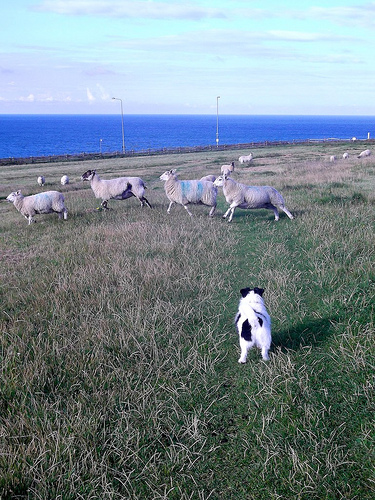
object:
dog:
[238, 283, 283, 375]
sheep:
[84, 166, 134, 195]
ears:
[240, 283, 274, 303]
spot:
[237, 318, 262, 343]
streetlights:
[103, 87, 226, 157]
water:
[2, 107, 88, 159]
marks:
[174, 179, 210, 203]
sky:
[64, 10, 194, 85]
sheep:
[217, 130, 374, 175]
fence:
[10, 148, 155, 166]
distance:
[103, 138, 372, 173]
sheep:
[77, 161, 158, 212]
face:
[76, 166, 106, 191]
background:
[54, 124, 367, 177]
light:
[108, 84, 139, 160]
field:
[73, 157, 252, 173]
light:
[205, 88, 230, 145]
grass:
[31, 235, 213, 418]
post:
[116, 96, 134, 151]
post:
[214, 102, 230, 146]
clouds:
[155, 17, 277, 64]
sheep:
[160, 157, 226, 220]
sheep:
[10, 185, 75, 231]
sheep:
[320, 140, 373, 178]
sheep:
[230, 146, 259, 171]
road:
[65, 147, 265, 162]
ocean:
[37, 98, 285, 155]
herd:
[35, 114, 285, 236]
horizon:
[15, 101, 326, 130]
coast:
[32, 144, 335, 167]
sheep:
[212, 170, 294, 218]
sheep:
[7, 186, 68, 223]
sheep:
[156, 168, 217, 217]